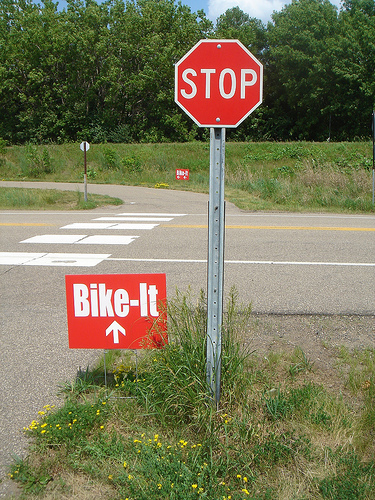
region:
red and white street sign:
[167, 34, 266, 133]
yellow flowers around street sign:
[31, 354, 252, 497]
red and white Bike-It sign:
[64, 272, 171, 388]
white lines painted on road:
[3, 203, 374, 283]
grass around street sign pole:
[147, 302, 256, 412]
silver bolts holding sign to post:
[214, 41, 225, 125]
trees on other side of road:
[4, 1, 373, 151]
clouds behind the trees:
[204, 4, 350, 36]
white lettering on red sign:
[177, 61, 255, 104]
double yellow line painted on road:
[1, 217, 371, 237]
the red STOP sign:
[174, 39, 262, 127]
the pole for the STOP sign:
[206, 126, 224, 405]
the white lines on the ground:
[0, 211, 373, 266]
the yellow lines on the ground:
[0, 222, 373, 231]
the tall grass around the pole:
[132, 284, 256, 430]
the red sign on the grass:
[64, 272, 168, 348]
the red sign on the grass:
[176, 168, 190, 180]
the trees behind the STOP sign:
[0, 0, 374, 143]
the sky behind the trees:
[0, 0, 373, 54]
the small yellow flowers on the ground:
[6, 353, 249, 499]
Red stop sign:
[177, 33, 268, 129]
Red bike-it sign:
[64, 268, 167, 362]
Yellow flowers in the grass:
[22, 389, 235, 498]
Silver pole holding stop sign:
[209, 129, 221, 397]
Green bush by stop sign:
[149, 303, 257, 416]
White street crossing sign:
[1, 212, 191, 272]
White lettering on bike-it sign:
[63, 266, 179, 360]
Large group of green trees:
[6, 6, 367, 138]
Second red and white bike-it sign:
[170, 159, 196, 189]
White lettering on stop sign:
[164, 26, 270, 135]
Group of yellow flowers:
[152, 178, 170, 187]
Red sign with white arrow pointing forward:
[63, 272, 166, 348]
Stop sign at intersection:
[173, 36, 260, 126]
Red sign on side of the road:
[172, 167, 187, 178]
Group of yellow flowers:
[8, 349, 248, 496]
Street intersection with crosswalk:
[0, 210, 184, 267]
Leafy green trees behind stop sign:
[0, 0, 371, 144]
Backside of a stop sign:
[80, 140, 89, 202]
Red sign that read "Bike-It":
[62, 272, 167, 347]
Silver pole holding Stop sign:
[206, 126, 225, 407]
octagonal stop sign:
[173, 37, 263, 129]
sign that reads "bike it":
[61, 269, 172, 355]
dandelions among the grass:
[1, 396, 257, 499]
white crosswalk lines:
[0, 204, 197, 271]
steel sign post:
[202, 128, 227, 401]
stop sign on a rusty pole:
[81, 141, 92, 201]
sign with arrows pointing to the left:
[174, 164, 190, 187]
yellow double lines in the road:
[3, 217, 374, 241]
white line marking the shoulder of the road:
[107, 253, 373, 271]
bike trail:
[1, 169, 241, 209]